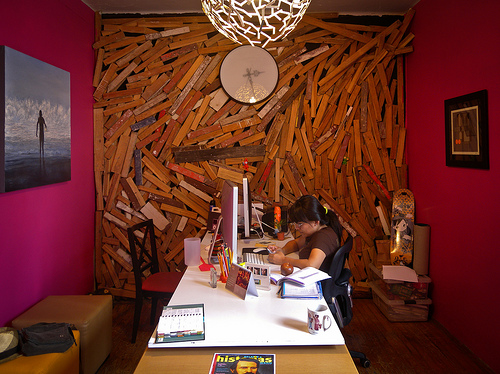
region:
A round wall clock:
[218, 43, 284, 105]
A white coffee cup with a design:
[297, 304, 342, 341]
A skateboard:
[385, 189, 420, 271]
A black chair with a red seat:
[122, 221, 186, 342]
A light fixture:
[195, 0, 313, 51]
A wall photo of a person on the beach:
[2, 44, 77, 197]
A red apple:
[274, 257, 299, 282]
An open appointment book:
[150, 301, 208, 350]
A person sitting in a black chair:
[260, 184, 367, 343]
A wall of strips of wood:
[93, 17, 425, 289]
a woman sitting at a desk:
[272, 185, 364, 268]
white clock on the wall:
[202, 37, 317, 131]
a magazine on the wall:
[197, 342, 280, 372]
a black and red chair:
[102, 197, 184, 345]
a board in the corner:
[386, 182, 420, 279]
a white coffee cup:
[296, 294, 336, 349]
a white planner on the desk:
[156, 296, 220, 357]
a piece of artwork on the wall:
[0, 47, 100, 200]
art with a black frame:
[419, 87, 499, 169]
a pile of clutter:
[343, 167, 442, 339]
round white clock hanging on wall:
[218, 43, 279, 105]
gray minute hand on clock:
[241, 67, 260, 102]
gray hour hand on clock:
[242, 65, 267, 78]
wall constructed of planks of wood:
[91, 12, 412, 298]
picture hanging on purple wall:
[2, 46, 76, 193]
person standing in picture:
[34, 108, 54, 158]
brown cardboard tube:
[413, 220, 433, 276]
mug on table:
[307, 304, 333, 334]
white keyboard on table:
[246, 250, 288, 272]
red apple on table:
[280, 260, 295, 276]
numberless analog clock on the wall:
[202, 37, 295, 115]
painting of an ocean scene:
[6, 47, 82, 194]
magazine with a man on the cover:
[202, 345, 287, 372]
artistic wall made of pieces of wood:
[99, 20, 406, 306]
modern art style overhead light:
[188, 10, 323, 54]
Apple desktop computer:
[211, 177, 273, 270]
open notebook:
[138, 295, 218, 365]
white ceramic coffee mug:
[288, 296, 346, 339]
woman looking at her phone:
[259, 188, 358, 312]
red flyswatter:
[188, 242, 225, 279]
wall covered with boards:
[91, 16, 413, 298]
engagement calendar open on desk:
[152, 303, 206, 343]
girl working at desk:
[266, 191, 346, 296]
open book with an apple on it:
[268, 258, 332, 286]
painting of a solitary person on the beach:
[3, 46, 73, 191]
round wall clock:
[216, 43, 281, 105]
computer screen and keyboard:
[219, 177, 281, 271]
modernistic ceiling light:
[198, 1, 310, 47]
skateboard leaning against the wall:
[389, 186, 416, 266]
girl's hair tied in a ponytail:
[266, 191, 346, 272]